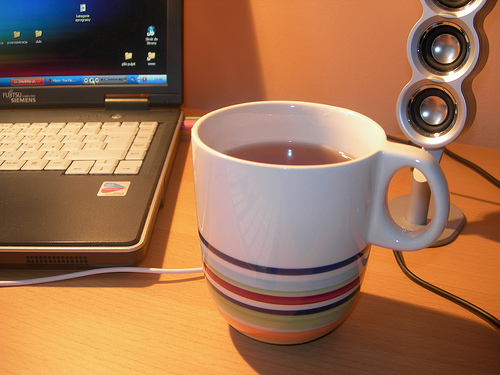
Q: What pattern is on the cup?
A: Stripes.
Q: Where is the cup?
A: Table.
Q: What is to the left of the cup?
A: Open laptop.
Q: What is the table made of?
A: Wood.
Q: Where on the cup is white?
A: The upper half.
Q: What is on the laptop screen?
A: Icons.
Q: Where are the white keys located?
A: On the laptop keyboard.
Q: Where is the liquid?
A: Inside cup.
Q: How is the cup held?
A: Handle.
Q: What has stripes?
A: Cup.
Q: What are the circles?
A: Speakers.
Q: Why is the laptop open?
A: To use.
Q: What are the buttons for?
A: To type on the laptop.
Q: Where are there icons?
A: Computer screen.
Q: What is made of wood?
A: Table.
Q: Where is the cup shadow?
A: Right side on table.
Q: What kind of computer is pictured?
A: A laptop.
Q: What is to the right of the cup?
A: A computer speaker.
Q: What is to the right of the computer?
A: A cup.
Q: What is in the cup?
A: Tea.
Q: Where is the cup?
A: On a desk.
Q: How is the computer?
A: On.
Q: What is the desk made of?
A: Wood.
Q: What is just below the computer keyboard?
A: A sticker with an Intel chip logo.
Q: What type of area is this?
A: A workspace.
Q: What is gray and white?
A: The keyboard.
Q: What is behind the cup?
A: Speakers.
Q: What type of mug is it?
A: A coffee mug.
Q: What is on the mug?
A: Stripes.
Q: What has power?
A: The laptop.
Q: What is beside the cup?
A: A cord.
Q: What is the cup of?
A: Coffee.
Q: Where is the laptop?
A: On the left side.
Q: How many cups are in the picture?
A: One.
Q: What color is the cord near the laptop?
A: White.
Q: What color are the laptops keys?
A: White.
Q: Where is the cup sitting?
A: On a table.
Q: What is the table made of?
A: Wood.